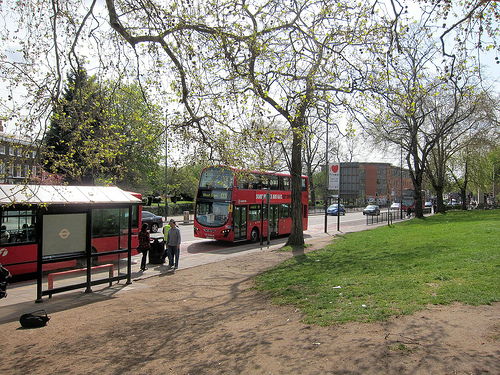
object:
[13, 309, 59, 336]
backpack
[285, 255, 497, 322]
grass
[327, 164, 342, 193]
banner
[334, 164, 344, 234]
pole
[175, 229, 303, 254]
sidewalk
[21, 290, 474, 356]
ground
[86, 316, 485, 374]
shade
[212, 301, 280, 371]
ground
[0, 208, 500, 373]
field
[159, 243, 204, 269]
jeans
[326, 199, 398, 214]
cars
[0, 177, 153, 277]
bus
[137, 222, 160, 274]
woman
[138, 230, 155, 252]
coat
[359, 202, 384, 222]
car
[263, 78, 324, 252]
tree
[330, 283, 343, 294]
trash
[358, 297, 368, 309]
trash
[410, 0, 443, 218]
tree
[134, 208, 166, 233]
dark car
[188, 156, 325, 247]
bus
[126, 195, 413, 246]
street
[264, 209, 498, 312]
area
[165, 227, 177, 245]
shirt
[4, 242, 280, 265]
sidewalk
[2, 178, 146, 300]
stop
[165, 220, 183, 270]
man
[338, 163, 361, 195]
windows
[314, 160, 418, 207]
building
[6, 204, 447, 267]
road